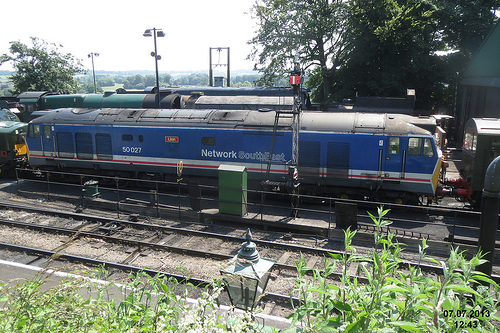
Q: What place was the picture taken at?
A: It was taken at the station.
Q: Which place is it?
A: It is a station.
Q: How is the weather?
A: It is clear.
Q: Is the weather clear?
A: Yes, it is clear.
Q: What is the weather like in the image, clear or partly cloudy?
A: It is clear.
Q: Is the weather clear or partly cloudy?
A: It is clear.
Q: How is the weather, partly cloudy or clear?
A: It is clear.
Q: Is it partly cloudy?
A: No, it is clear.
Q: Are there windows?
A: Yes, there is a window.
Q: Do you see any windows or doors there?
A: Yes, there is a window.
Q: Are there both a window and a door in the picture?
A: Yes, there are both a window and a door.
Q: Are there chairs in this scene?
A: No, there are no chairs.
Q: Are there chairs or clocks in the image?
A: No, there are no chairs or clocks.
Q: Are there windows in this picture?
A: Yes, there is a window.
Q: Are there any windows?
A: Yes, there is a window.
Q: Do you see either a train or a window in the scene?
A: Yes, there is a window.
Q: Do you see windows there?
A: Yes, there is a window.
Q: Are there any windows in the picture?
A: Yes, there is a window.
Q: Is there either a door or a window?
A: Yes, there is a window.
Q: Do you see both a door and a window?
A: Yes, there are both a window and a door.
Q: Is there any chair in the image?
A: No, there are no chairs.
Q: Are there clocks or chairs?
A: No, there are no chairs or clocks.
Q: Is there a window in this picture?
A: Yes, there is a window.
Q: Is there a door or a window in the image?
A: Yes, there is a window.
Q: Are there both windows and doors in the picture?
A: Yes, there are both a window and a door.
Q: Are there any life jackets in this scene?
A: No, there are no life jackets.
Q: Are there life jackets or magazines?
A: No, there are no life jackets or magazines.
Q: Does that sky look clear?
A: Yes, the sky is clear.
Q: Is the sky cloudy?
A: No, the sky is clear.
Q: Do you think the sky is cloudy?
A: No, the sky is clear.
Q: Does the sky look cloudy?
A: No, the sky is clear.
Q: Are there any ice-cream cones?
A: No, there are no ice-cream cones.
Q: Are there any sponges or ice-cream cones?
A: No, there are no ice-cream cones or sponges.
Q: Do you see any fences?
A: Yes, there is a fence.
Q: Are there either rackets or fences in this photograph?
A: Yes, there is a fence.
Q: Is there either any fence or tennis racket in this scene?
A: Yes, there is a fence.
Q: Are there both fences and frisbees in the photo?
A: No, there is a fence but no frisbees.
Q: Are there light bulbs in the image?
A: No, there are no light bulbs.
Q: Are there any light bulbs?
A: No, there are no light bulbs.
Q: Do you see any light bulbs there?
A: No, there are no light bulbs.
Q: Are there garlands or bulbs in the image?
A: No, there are no bulbs or garlands.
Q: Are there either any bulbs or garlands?
A: No, there are no bulbs or garlands.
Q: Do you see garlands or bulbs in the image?
A: No, there are no bulbs or garlands.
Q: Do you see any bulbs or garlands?
A: No, there are no bulbs or garlands.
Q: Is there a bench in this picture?
A: No, there are no benches.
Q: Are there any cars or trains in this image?
A: Yes, there is a train.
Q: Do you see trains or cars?
A: Yes, there is a train.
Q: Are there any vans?
A: No, there are no vans.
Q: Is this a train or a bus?
A: This is a train.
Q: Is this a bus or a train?
A: This is a train.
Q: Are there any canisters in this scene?
A: No, there are no canisters.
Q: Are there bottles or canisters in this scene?
A: No, there are no canisters or bottles.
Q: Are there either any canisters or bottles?
A: No, there are no canisters or bottles.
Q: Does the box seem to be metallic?
A: Yes, the box is metallic.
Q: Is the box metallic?
A: Yes, the box is metallic.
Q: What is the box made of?
A: The box is made of metal.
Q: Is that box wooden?
A: No, the box is metallic.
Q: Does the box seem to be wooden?
A: No, the box is metallic.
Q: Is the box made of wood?
A: No, the box is made of metal.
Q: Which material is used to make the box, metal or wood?
A: The box is made of metal.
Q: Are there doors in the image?
A: Yes, there is a door.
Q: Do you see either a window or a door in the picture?
A: Yes, there is a door.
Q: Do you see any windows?
A: Yes, there is a window.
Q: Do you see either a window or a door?
A: Yes, there is a window.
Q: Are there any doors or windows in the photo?
A: Yes, there is a window.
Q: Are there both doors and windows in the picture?
A: Yes, there are both a window and a door.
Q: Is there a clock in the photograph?
A: No, there are no clocks.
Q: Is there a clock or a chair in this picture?
A: No, there are no clocks or chairs.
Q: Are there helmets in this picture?
A: No, there are no helmets.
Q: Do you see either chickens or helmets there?
A: No, there are no helmets or chickens.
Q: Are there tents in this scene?
A: No, there are no tents.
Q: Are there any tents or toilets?
A: No, there are no tents or toilets.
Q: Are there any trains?
A: Yes, there is a train.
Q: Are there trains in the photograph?
A: Yes, there is a train.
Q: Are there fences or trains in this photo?
A: Yes, there is a train.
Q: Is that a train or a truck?
A: That is a train.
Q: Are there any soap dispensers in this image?
A: No, there are no soap dispensers.